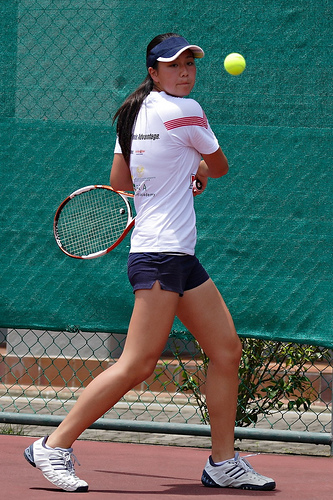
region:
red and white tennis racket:
[52, 181, 203, 263]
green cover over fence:
[0, 0, 331, 357]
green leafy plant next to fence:
[147, 312, 332, 450]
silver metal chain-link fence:
[1, 0, 332, 448]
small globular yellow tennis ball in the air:
[221, 51, 247, 77]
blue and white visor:
[145, 33, 204, 63]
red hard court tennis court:
[0, 430, 332, 499]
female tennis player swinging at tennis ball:
[21, 31, 277, 494]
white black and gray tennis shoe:
[197, 452, 279, 494]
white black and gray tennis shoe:
[22, 433, 89, 492]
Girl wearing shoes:
[15, 431, 282, 497]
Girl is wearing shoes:
[16, 429, 278, 493]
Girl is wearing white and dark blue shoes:
[14, 433, 286, 494]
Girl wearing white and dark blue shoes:
[20, 431, 279, 495]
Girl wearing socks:
[42, 430, 238, 467]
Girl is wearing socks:
[43, 433, 238, 469]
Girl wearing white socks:
[41, 438, 236, 467]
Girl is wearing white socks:
[39, 438, 239, 467]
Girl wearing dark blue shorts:
[126, 246, 214, 296]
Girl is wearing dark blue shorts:
[123, 244, 218, 302]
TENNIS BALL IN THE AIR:
[223, 57, 242, 79]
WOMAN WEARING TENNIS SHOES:
[199, 454, 283, 490]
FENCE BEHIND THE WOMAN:
[143, 401, 161, 417]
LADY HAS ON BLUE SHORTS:
[169, 257, 186, 276]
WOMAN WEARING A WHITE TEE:
[162, 220, 181, 239]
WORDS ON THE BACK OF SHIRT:
[133, 131, 156, 202]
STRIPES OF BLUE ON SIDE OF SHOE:
[230, 464, 232, 472]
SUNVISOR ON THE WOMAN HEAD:
[160, 35, 189, 57]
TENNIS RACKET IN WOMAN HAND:
[194, 181, 202, 191]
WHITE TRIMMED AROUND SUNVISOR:
[180, 46, 190, 48]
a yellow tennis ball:
[223, 52, 246, 76]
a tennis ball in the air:
[218, 46, 247, 80]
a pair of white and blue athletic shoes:
[23, 432, 276, 492]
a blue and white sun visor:
[145, 37, 204, 63]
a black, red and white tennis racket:
[52, 184, 131, 259]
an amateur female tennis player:
[22, 32, 276, 492]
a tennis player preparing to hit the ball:
[22, 32, 277, 492]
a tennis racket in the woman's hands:
[52, 172, 208, 259]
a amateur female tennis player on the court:
[3, 21, 329, 492]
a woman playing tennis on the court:
[7, 31, 324, 492]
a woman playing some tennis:
[50, 37, 286, 497]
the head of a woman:
[139, 39, 199, 98]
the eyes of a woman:
[159, 54, 191, 70]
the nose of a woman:
[176, 68, 190, 82]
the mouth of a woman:
[170, 75, 194, 89]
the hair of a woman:
[111, 80, 150, 144]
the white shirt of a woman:
[127, 94, 208, 246]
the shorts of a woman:
[125, 247, 210, 300]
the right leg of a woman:
[53, 272, 175, 437]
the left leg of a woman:
[173, 287, 263, 453]